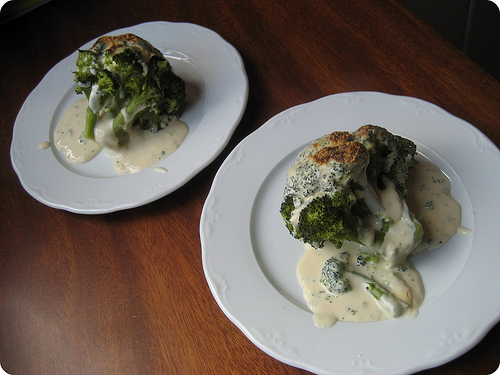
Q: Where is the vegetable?
A: On plates.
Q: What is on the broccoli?
A: A Sauce.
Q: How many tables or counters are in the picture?
A: One.